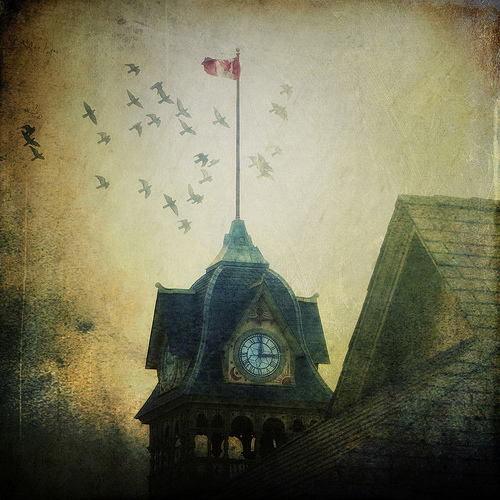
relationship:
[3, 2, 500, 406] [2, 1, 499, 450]
part of sky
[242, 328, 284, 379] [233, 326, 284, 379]
edge of clock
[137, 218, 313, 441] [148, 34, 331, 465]
part of tower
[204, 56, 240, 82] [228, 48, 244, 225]
flag on pole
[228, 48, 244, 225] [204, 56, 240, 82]
pole for flag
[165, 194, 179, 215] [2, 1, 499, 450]
bird in sky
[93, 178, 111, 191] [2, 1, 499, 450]
bird in sky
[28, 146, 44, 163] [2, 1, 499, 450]
bird in sky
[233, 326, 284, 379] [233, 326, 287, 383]
part of a clock